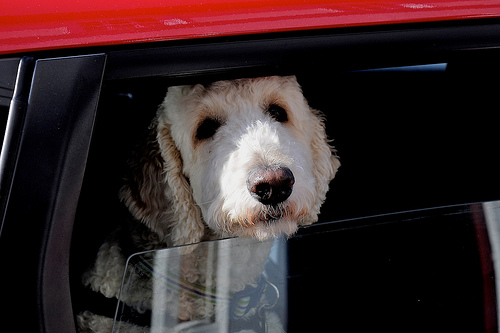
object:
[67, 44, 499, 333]
window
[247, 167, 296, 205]
nose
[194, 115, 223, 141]
eye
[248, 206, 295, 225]
mouth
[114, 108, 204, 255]
ear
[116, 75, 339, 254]
head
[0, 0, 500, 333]
car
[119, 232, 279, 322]
collar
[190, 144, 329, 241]
snout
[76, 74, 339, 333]
dog